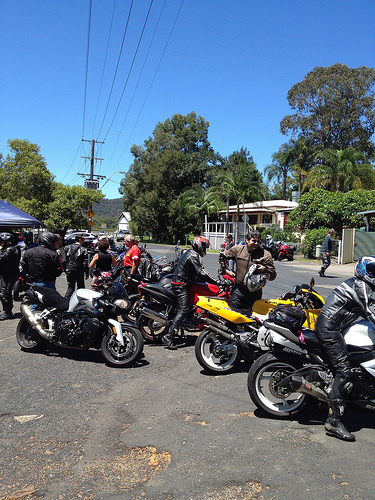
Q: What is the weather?
A: Sunny.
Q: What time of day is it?
A: Daytime.